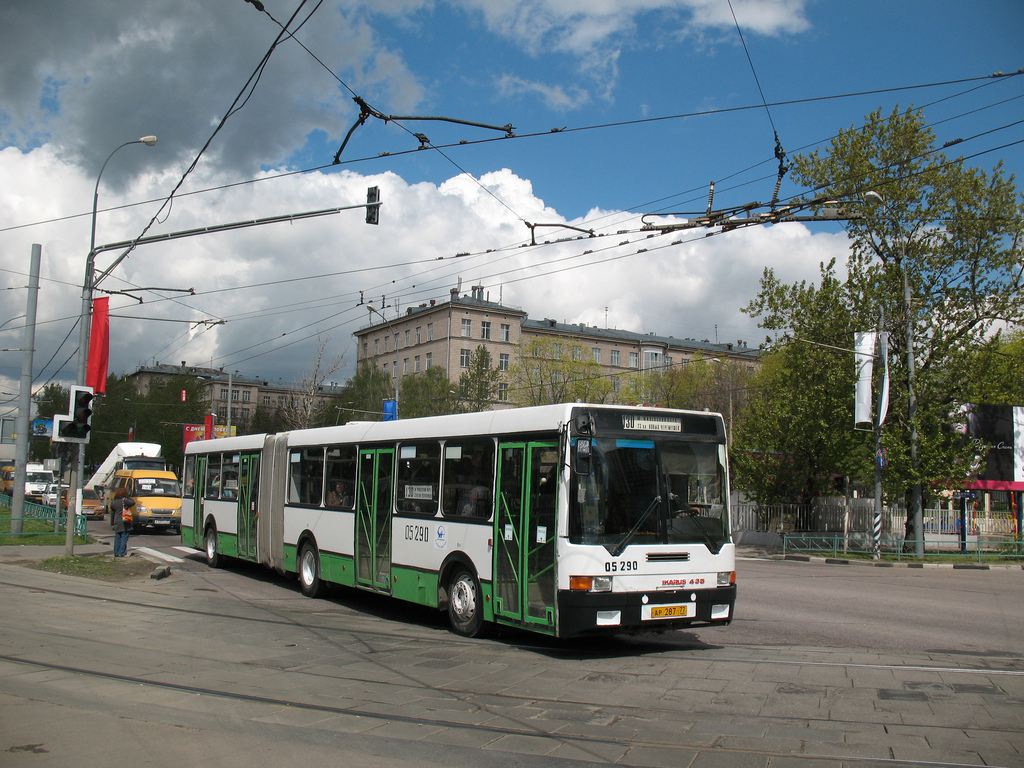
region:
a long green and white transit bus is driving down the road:
[170, 401, 746, 646]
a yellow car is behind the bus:
[108, 465, 185, 532]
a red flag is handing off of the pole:
[81, 293, 114, 402]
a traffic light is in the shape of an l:
[51, 379, 105, 450]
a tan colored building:
[354, 288, 781, 416]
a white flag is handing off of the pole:
[849, 328, 894, 437]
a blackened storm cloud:
[3, 3, 430, 184]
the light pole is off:
[63, 129, 166, 564]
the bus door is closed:
[496, 437, 557, 624]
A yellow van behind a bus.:
[108, 465, 182, 538]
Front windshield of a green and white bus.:
[572, 440, 731, 549]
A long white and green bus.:
[177, 400, 740, 639]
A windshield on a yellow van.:
[131, 475, 180, 496]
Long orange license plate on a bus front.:
[649, 599, 689, 625]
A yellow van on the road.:
[108, 465, 182, 533]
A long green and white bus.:
[178, 403, 738, 642]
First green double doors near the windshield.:
[488, 441, 561, 629]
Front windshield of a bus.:
[566, 440, 732, 554]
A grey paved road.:
[7, 511, 1014, 767]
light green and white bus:
[175, 404, 735, 636]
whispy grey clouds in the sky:
[5, 14, 394, 183]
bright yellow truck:
[107, 468, 183, 530]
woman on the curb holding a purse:
[103, 482, 142, 558]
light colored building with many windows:
[363, 291, 759, 408]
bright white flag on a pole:
[853, 326, 893, 435]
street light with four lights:
[50, 384, 95, 445]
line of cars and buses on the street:
[8, 408, 751, 647]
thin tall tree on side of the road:
[750, 111, 1020, 542]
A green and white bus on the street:
[177, 396, 735, 654]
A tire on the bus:
[432, 544, 489, 646]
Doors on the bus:
[486, 433, 566, 640]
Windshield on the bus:
[567, 404, 733, 542]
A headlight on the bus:
[584, 572, 617, 595]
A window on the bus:
[397, 442, 445, 528]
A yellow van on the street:
[107, 463, 178, 536]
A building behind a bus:
[347, 294, 791, 412]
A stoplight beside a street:
[49, 368, 111, 556]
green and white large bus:
[188, 447, 577, 593]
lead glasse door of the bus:
[494, 444, 561, 609]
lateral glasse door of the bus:
[368, 452, 400, 592]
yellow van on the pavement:
[121, 468, 176, 523]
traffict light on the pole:
[69, 387, 102, 442]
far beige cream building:
[368, 323, 501, 363]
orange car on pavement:
[85, 494, 99, 521]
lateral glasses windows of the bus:
[400, 446, 484, 522]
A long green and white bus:
[166, 396, 752, 662]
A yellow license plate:
[639, 589, 693, 628]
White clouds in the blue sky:
[1, 0, 1016, 403]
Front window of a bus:
[554, 421, 735, 554]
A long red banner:
[73, 282, 122, 401]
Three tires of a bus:
[184, 501, 491, 642]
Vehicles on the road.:
[27, 383, 1020, 753]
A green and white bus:
[160, 422, 743, 651]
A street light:
[83, 115, 166, 536]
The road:
[20, 455, 1016, 759]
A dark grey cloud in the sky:
[2, 7, 439, 210]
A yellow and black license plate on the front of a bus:
[647, 601, 701, 621]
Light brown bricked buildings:
[132, 295, 856, 447]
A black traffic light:
[58, 380, 97, 456]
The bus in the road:
[179, 406, 750, 650]